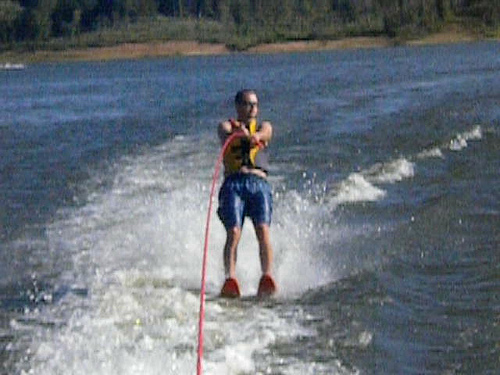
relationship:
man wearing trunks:
[214, 88, 274, 295] [212, 174, 274, 228]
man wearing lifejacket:
[201, 72, 286, 324] [215, 113, 277, 173]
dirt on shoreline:
[151, 32, 352, 56] [5, 15, 499, 62]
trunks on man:
[212, 170, 275, 228] [214, 88, 274, 295]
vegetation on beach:
[2, 6, 485, 90] [0, 33, 498, 67]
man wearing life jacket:
[214, 88, 274, 295] [245, 147, 267, 171]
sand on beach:
[128, 42, 222, 51] [6, 24, 498, 58]